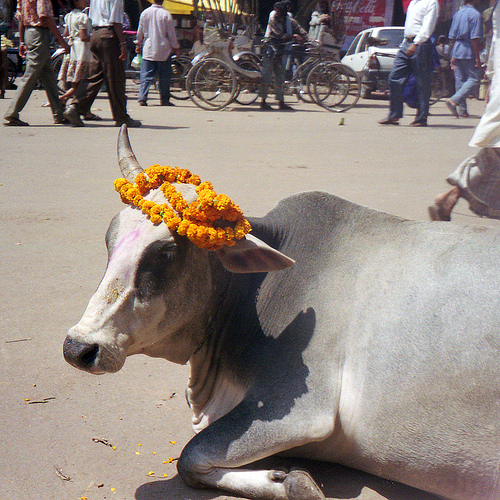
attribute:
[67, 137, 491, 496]
cow — sitting, lying, laying, large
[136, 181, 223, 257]
flower — orange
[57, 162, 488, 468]
animal — large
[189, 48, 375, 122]
bicycle — held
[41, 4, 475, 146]
people — walking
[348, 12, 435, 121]
car — white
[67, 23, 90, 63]
dress — white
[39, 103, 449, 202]
street — busy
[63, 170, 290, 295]
wreath — orange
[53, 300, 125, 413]
nose — black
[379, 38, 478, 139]
pants — blue, grey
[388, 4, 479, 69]
shirt — white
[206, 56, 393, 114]
bike — here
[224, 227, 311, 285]
ear — large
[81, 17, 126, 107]
pants — brown